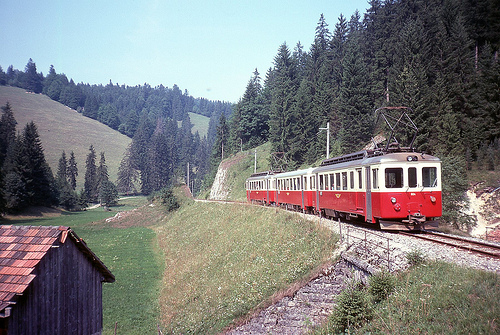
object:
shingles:
[6, 221, 85, 325]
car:
[244, 150, 442, 231]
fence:
[345, 226, 391, 270]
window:
[407, 167, 417, 189]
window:
[422, 167, 437, 187]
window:
[385, 168, 404, 188]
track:
[194, 199, 499, 258]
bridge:
[188, 181, 195, 197]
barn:
[0, 225, 117, 335]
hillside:
[4, 57, 219, 221]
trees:
[233, 67, 271, 144]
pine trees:
[34, 65, 244, 212]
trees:
[266, 42, 309, 165]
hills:
[197, 71, 345, 206]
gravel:
[390, 233, 438, 259]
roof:
[0, 224, 74, 303]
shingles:
[5, 210, 66, 274]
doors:
[365, 166, 372, 220]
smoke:
[185, 101, 219, 169]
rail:
[395, 221, 493, 261]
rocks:
[396, 230, 500, 268]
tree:
[93, 179, 121, 208]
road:
[81, 199, 100, 212]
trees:
[0, 58, 84, 107]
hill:
[0, 103, 124, 188]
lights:
[391, 198, 397, 203]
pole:
[326, 123, 330, 158]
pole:
[254, 150, 257, 173]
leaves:
[331, 82, 365, 114]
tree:
[331, 52, 363, 154]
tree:
[288, 85, 325, 163]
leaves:
[292, 92, 305, 142]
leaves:
[404, 89, 424, 149]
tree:
[384, 21, 431, 148]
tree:
[454, 69, 500, 169]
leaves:
[440, 77, 462, 120]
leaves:
[166, 194, 176, 209]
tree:
[156, 188, 183, 213]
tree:
[148, 130, 170, 195]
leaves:
[156, 149, 165, 191]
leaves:
[101, 182, 111, 204]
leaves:
[89, 167, 103, 194]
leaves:
[27, 142, 49, 190]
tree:
[0, 103, 52, 215]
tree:
[85, 144, 107, 203]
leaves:
[97, 186, 109, 199]